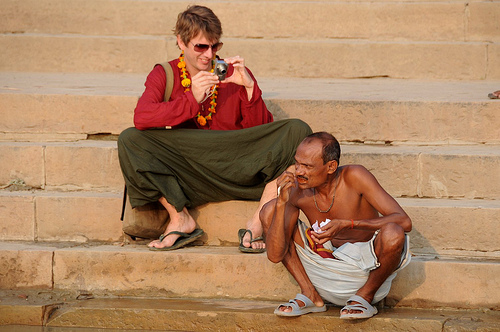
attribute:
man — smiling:
[118, 5, 313, 249]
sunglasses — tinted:
[188, 37, 223, 53]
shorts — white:
[294, 220, 416, 308]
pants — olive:
[117, 118, 315, 211]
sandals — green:
[147, 228, 269, 255]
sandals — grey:
[274, 291, 380, 320]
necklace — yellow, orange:
[176, 55, 219, 127]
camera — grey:
[213, 60, 229, 82]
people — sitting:
[120, 5, 412, 320]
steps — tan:
[1, 1, 494, 329]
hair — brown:
[174, 6, 221, 33]